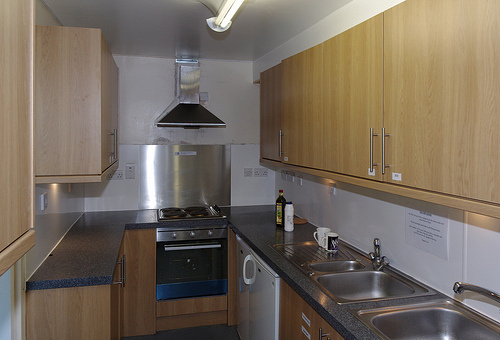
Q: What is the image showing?
A: It is showing a kitchen.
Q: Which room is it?
A: It is a kitchen.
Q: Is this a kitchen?
A: Yes, it is a kitchen.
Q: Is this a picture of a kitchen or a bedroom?
A: It is showing a kitchen.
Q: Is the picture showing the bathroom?
A: No, the picture is showing the kitchen.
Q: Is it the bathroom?
A: No, it is the kitchen.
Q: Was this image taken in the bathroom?
A: No, the picture was taken in the kitchen.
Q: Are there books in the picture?
A: No, there are no books.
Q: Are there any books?
A: No, there are no books.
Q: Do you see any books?
A: No, there are no books.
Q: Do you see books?
A: No, there are no books.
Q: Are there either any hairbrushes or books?
A: No, there are no books or hairbrushes.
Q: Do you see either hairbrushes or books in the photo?
A: No, there are no books or hairbrushes.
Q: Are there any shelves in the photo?
A: No, there are no shelves.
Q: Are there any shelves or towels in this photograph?
A: No, there are no shelves or towels.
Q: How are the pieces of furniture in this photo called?
A: The pieces of furniture are cabinets.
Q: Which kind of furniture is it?
A: The pieces of furniture are cabinets.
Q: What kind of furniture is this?
A: These are cabinets.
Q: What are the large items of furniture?
A: The pieces of furniture are cabinets.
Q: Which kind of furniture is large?
A: The furniture is cabinets.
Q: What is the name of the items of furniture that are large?
A: The pieces of furniture are cabinets.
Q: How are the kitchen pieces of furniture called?
A: The pieces of furniture are cabinets.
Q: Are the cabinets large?
A: Yes, the cabinets are large.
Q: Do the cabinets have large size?
A: Yes, the cabinets are large.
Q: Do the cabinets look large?
A: Yes, the cabinets are large.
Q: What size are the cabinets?
A: The cabinets are large.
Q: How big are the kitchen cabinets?
A: The cabinets are large.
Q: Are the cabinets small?
A: No, the cabinets are large.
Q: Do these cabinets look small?
A: No, the cabinets are large.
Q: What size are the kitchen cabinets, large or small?
A: The cabinets are large.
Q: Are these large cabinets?
A: Yes, these are large cabinets.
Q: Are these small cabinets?
A: No, these are large cabinets.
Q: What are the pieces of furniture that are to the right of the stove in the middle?
A: The pieces of furniture are cabinets.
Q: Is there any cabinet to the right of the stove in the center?
A: Yes, there are cabinets to the right of the stove.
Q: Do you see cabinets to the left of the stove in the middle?
A: No, the cabinets are to the right of the stove.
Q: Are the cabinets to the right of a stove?
A: Yes, the cabinets are to the right of a stove.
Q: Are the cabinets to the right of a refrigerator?
A: No, the cabinets are to the right of a stove.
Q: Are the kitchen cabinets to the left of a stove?
A: No, the cabinets are to the right of a stove.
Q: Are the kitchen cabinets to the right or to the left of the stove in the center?
A: The cabinets are to the right of the stove.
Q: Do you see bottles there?
A: Yes, there is a bottle.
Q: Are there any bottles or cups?
A: Yes, there is a bottle.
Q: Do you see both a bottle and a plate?
A: No, there is a bottle but no plates.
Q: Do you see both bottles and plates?
A: No, there is a bottle but no plates.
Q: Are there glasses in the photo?
A: No, there are no glasses.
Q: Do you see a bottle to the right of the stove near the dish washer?
A: Yes, there is a bottle to the right of the stove.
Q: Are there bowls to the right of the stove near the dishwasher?
A: No, there is a bottle to the right of the stove.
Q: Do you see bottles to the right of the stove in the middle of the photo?
A: Yes, there is a bottle to the right of the stove.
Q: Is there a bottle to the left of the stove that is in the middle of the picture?
A: No, the bottle is to the right of the stove.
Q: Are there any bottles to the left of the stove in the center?
A: No, the bottle is to the right of the stove.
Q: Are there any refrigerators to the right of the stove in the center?
A: No, there is a bottle to the right of the stove.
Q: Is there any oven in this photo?
A: Yes, there is an oven.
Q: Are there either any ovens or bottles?
A: Yes, there is an oven.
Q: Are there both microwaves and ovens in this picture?
A: No, there is an oven but no microwaves.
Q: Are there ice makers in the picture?
A: No, there are no ice makers.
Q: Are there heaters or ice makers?
A: No, there are no ice makers or heaters.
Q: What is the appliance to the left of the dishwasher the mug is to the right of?
A: The appliance is an oven.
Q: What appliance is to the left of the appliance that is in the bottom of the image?
A: The appliance is an oven.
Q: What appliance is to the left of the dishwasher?
A: The appliance is an oven.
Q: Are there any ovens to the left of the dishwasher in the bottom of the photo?
A: Yes, there is an oven to the left of the dishwasher.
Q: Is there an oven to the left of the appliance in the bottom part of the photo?
A: Yes, there is an oven to the left of the dishwasher.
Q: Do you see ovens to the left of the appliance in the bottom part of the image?
A: Yes, there is an oven to the left of the dishwasher.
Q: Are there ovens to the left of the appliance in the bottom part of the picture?
A: Yes, there is an oven to the left of the dishwasher.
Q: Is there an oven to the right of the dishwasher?
A: No, the oven is to the left of the dishwasher.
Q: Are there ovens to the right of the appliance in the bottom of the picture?
A: No, the oven is to the left of the dishwasher.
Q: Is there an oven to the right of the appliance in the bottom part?
A: No, the oven is to the left of the dishwasher.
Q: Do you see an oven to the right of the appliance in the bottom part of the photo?
A: No, the oven is to the left of the dishwasher.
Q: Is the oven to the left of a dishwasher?
A: Yes, the oven is to the left of a dishwasher.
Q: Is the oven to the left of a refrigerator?
A: No, the oven is to the left of a dishwasher.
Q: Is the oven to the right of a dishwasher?
A: No, the oven is to the left of a dishwasher.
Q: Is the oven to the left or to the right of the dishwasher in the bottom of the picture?
A: The oven is to the left of the dishwasher.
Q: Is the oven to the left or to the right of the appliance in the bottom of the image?
A: The oven is to the left of the dishwasher.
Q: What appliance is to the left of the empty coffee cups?
A: The appliance is an oven.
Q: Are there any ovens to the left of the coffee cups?
A: Yes, there is an oven to the left of the coffee cups.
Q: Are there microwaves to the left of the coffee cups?
A: No, there is an oven to the left of the coffee cups.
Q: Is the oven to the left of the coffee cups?
A: Yes, the oven is to the left of the coffee cups.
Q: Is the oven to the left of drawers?
A: No, the oven is to the left of the coffee cups.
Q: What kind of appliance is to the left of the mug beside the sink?
A: The appliance is an oven.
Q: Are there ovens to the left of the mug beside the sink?
A: Yes, there is an oven to the left of the mug.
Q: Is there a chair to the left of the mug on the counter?
A: No, there is an oven to the left of the mug.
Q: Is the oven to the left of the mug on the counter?
A: Yes, the oven is to the left of the mug.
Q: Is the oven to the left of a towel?
A: No, the oven is to the left of the mug.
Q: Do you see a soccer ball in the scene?
A: No, there are no soccer balls.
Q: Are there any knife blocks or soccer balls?
A: No, there are no soccer balls or knife blocks.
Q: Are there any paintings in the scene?
A: No, there are no paintings.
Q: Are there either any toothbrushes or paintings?
A: No, there are no paintings or toothbrushes.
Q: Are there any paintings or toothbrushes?
A: No, there are no paintings or toothbrushes.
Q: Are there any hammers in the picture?
A: No, there are no hammers.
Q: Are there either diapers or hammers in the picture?
A: No, there are no hammers or diapers.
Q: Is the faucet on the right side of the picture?
A: Yes, the faucet is on the right of the image.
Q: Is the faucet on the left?
A: No, the faucet is on the right of the image.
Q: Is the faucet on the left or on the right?
A: The faucet is on the right of the image.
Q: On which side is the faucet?
A: The faucet is on the right of the image.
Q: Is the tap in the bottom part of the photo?
A: Yes, the tap is in the bottom of the image.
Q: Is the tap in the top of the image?
A: No, the tap is in the bottom of the image.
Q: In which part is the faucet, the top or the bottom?
A: The faucet is in the bottom of the image.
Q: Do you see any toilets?
A: No, there are no toilets.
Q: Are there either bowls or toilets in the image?
A: No, there are no toilets or bowls.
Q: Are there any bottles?
A: Yes, there is a bottle.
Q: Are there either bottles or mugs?
A: Yes, there is a bottle.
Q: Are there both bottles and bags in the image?
A: No, there is a bottle but no bags.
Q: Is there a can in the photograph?
A: No, there are no cans.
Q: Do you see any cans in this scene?
A: No, there are no cans.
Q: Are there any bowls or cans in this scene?
A: No, there are no cans or bowls.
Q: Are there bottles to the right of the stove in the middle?
A: Yes, there is a bottle to the right of the stove.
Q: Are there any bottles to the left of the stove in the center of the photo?
A: No, the bottle is to the right of the stove.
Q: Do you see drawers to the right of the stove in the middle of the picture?
A: No, there is a bottle to the right of the stove.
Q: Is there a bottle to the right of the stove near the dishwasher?
A: Yes, there is a bottle to the right of the stove.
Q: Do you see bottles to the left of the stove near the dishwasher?
A: No, the bottle is to the right of the stove.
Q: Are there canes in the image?
A: No, there are no canes.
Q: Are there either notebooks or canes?
A: No, there are no canes or notebooks.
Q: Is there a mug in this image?
A: Yes, there is a mug.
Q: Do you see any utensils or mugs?
A: Yes, there is a mug.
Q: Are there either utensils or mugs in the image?
A: Yes, there is a mug.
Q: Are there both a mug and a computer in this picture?
A: No, there is a mug but no computers.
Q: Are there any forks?
A: No, there are no forks.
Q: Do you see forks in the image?
A: No, there are no forks.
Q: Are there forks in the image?
A: No, there are no forks.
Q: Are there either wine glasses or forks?
A: No, there are no forks or wine glasses.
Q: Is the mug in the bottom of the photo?
A: Yes, the mug is in the bottom of the image.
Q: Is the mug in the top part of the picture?
A: No, the mug is in the bottom of the image.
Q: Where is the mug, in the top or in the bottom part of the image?
A: The mug is in the bottom of the image.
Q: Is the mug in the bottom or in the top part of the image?
A: The mug is in the bottom of the image.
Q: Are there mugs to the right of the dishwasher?
A: Yes, there is a mug to the right of the dishwasher.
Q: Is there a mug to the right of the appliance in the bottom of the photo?
A: Yes, there is a mug to the right of the dishwasher.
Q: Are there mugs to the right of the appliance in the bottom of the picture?
A: Yes, there is a mug to the right of the dishwasher.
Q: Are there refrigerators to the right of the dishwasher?
A: No, there is a mug to the right of the dishwasher.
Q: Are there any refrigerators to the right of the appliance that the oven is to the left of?
A: No, there is a mug to the right of the dishwasher.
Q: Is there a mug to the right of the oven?
A: Yes, there is a mug to the right of the oven.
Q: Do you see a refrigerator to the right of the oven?
A: No, there is a mug to the right of the oven.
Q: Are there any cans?
A: No, there are no cans.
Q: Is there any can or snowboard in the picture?
A: No, there are no cans or snowboards.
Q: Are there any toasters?
A: No, there are no toasters.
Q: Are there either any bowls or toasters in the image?
A: No, there are no toasters or bowls.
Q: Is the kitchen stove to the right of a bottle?
A: No, the stove is to the left of a bottle.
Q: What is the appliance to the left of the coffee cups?
A: The appliance is a stove.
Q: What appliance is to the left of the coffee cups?
A: The appliance is a stove.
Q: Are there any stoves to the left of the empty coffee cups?
A: Yes, there is a stove to the left of the coffee cups.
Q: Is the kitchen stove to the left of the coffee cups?
A: Yes, the stove is to the left of the coffee cups.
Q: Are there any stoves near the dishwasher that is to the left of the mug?
A: Yes, there is a stove near the dish washer.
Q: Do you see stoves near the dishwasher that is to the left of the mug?
A: Yes, there is a stove near the dish washer.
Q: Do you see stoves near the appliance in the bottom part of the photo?
A: Yes, there is a stove near the dish washer.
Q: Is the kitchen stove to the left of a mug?
A: Yes, the stove is to the left of a mug.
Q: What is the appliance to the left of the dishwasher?
A: The appliance is a stove.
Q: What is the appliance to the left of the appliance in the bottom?
A: The appliance is a stove.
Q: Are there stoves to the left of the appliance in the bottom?
A: Yes, there is a stove to the left of the dishwasher.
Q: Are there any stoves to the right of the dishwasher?
A: No, the stove is to the left of the dishwasher.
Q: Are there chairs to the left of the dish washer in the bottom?
A: No, there is a stove to the left of the dishwasher.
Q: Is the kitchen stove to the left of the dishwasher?
A: Yes, the stove is to the left of the dishwasher.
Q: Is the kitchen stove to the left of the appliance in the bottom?
A: Yes, the stove is to the left of the dishwasher.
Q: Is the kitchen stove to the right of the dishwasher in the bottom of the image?
A: No, the stove is to the left of the dishwasher.